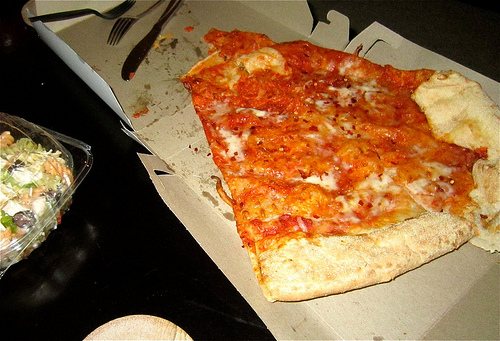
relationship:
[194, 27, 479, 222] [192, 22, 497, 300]
sauce with pizza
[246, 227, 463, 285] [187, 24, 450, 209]
crust on pizza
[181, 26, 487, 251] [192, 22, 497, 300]
cheese on pizza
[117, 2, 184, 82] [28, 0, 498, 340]
knife in a box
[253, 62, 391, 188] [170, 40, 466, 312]
sauce on pizza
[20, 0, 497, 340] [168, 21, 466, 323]
box with pizza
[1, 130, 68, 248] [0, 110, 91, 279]
salad in a container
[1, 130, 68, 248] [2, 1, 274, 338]
salad on table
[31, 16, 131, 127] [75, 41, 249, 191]
trim on box